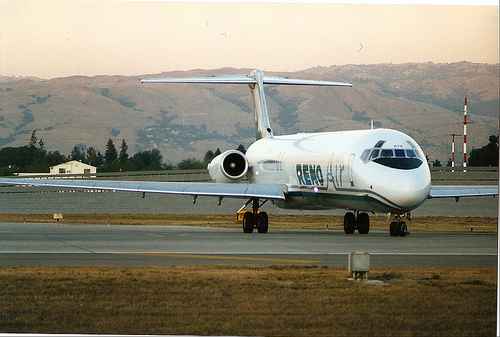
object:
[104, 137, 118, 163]
tree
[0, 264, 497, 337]
field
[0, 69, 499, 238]
plane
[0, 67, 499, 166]
mountains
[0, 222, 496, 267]
tarmac